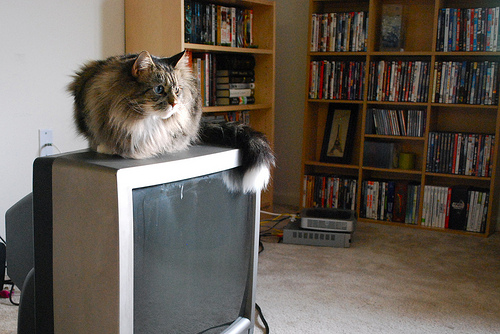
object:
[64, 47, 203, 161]
cat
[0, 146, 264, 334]
television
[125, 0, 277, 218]
shelf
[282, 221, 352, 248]
boxes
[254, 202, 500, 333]
carpet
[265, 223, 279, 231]
cords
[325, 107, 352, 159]
artwork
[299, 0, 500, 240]
shelf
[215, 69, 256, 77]
books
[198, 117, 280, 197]
tail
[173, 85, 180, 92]
eyes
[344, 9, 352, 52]
dvds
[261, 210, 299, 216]
cable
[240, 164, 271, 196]
white tip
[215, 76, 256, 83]
books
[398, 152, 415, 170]
cup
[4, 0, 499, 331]
room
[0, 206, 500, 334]
floor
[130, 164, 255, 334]
screen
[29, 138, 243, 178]
top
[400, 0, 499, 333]
ahead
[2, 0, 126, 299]
wall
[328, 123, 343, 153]
eiffel tower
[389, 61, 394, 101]
video games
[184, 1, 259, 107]
movies and books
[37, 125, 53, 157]
outlet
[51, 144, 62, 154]
cable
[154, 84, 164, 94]
blue eye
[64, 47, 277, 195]
fur